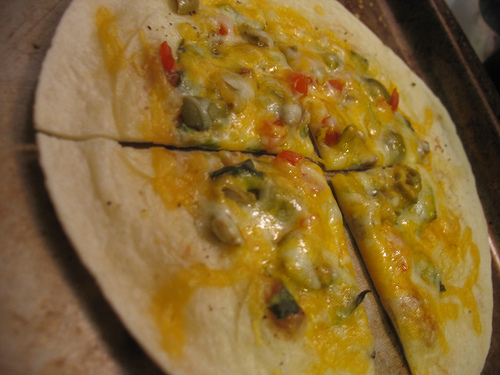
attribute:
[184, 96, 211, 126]
peppers — chopped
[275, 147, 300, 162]
peppers — chopped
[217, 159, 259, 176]
peppers — chopped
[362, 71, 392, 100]
peppers — chopped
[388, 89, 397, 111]
peppers — chopped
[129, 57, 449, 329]
quesadilla — half sliced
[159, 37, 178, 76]
tomato — chopped, red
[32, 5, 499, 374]
quesadilla — half sliced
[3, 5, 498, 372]
grill — flat-top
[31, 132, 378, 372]
slice — horizontal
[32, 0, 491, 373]
food — cooked, banked, white, baked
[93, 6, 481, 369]
glaze — yellow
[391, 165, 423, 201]
jalapeno slice — green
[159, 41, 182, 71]
pepper — red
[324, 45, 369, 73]
vegetables — green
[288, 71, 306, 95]
tomatoes — chopped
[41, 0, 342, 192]
quesadilla — round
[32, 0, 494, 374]
tortilla — flour, white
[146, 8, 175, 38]
spots — dark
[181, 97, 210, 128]
vegetable — green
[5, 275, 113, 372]
marks — brown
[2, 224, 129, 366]
pan — metal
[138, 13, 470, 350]
cheese — orange, white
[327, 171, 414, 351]
cheese — yellow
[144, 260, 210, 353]
cheese — yellow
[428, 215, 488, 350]
cheese — yellow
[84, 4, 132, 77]
cheese — yellow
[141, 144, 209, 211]
cheese — yellow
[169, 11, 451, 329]
cheese — melted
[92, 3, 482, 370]
sauce — yellow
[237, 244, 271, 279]
sauce — yellow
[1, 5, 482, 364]
table — brown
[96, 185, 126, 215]
fleck — brown